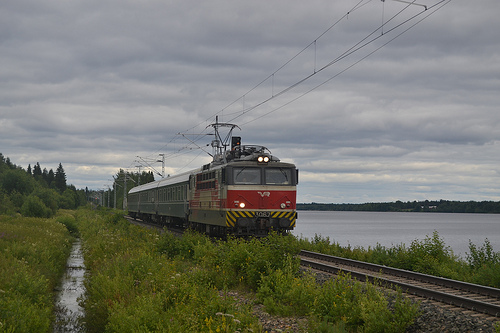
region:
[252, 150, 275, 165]
lights on the top of a train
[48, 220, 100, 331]
a small river in the ground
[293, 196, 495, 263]
body of water by the train tracks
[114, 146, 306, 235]
a train on the tracks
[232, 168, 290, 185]
a windshield of a train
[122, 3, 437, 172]
cables in the sky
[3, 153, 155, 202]
trees in the distance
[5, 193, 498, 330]
green vegetation on the ground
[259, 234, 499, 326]
train tracks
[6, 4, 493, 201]
gray clouds covering the sky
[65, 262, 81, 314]
creek near the tracks.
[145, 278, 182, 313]
weeds near the tracks.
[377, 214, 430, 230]
lake near the tracks.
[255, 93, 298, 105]
cables above the train.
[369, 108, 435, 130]
clouds in the sky.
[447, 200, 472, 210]
trees across the lake.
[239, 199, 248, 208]
headlight on the train.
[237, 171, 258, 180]
windshield on the train.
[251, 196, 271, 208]
red paint on the train.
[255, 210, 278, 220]
number on the train.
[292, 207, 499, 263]
a stretch of calm sea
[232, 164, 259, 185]
a window on a train car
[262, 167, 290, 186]
window on a train car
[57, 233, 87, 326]
a run of stagnant water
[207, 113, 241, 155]
a support for wires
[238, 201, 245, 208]
headlight on a train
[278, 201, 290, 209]
headlight on a train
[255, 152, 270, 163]
headlights ona train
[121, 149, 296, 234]
red light rail passenger train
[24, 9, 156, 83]
white clouds in blue sky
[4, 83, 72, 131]
white clouds in blue sky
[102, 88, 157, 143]
white clouds in blue sky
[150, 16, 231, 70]
white clouds in blue sky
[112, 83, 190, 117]
white clouds in blue sky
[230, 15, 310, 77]
white clouds in blue sky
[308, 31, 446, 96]
white clouds in blue sky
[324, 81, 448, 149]
white clouds in blue sky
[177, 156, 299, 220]
red train on tracks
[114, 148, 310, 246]
a train traveling to the right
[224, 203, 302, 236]
bumper of train is color yellow and black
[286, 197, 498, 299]
body of water next a railroad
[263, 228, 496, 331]
a railroad near a body of water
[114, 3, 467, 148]
power lines over a train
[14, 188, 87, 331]
a creek near a railroad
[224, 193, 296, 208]
headlights of train on a red background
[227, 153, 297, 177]
two lights on front of roof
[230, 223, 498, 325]
weeds on side railroad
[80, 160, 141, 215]
light pole on right side of railroad